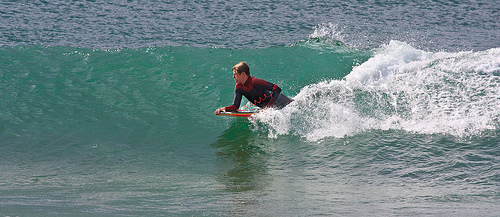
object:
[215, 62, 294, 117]
surfer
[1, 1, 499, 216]
water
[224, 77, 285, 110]
suit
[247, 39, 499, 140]
splashing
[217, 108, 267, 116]
surfboard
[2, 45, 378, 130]
wave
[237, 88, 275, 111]
cable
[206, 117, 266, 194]
shadow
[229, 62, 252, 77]
hair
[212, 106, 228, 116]
hand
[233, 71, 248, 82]
face